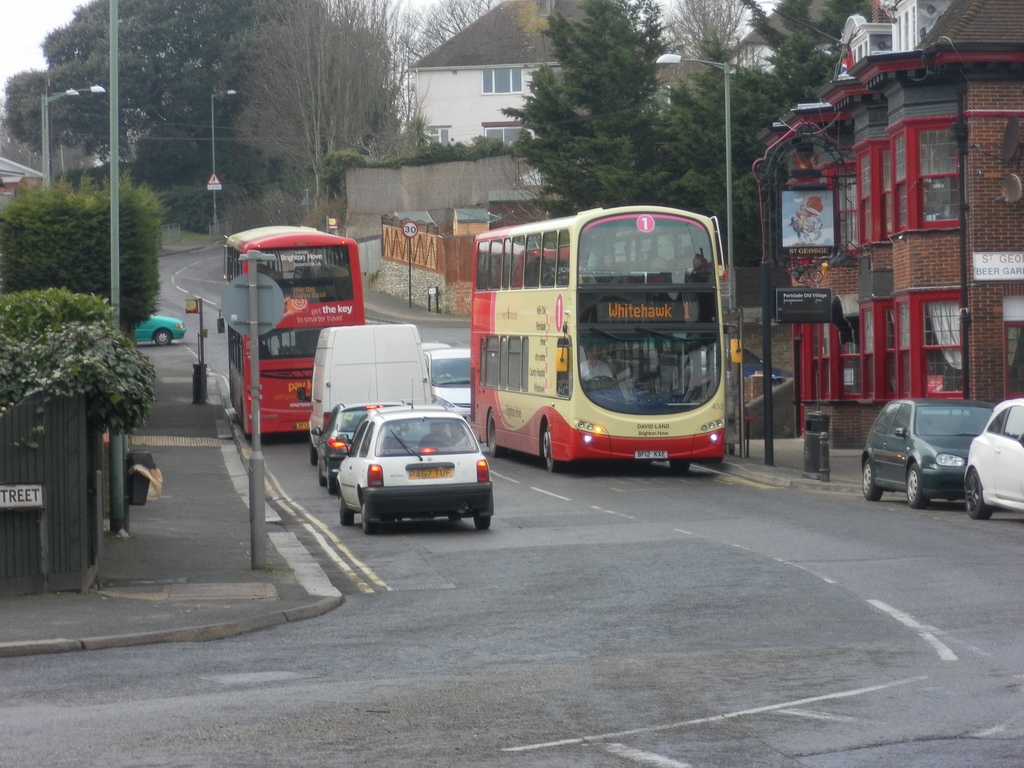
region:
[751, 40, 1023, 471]
red brick pub with red painted windows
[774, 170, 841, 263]
pub sign hanging in front of a pub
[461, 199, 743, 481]
yellow and red bus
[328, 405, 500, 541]
small light car has its brake lights on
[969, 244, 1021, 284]
pub sign advertises a beer garden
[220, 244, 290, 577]
circular traffic sign on a grey metal post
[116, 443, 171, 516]
grey trash can with a plastic bag inside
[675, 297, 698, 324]
bus number is displayed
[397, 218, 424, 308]
speed limit sign on the sidewalk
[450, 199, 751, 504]
The two level bus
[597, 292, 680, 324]
The digital display on the bus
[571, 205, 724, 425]
The large windshield on the bus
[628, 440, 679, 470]
The license plate on the bus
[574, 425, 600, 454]
The left headlight on the bus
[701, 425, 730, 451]
The right headlight on the bus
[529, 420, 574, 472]
The front wheel of the bus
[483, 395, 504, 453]
The back wheel of the bus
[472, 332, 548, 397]
The row of windows on the bus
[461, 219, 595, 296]
A row of windows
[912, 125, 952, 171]
glass window on the building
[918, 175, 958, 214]
glass window on the building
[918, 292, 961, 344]
glass window on the building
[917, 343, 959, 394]
glass window on the building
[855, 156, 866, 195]
glass window on the building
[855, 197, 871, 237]
glass window on the building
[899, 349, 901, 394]
glass window on the building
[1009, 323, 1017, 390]
glass window on the building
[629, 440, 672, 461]
license plate on the bus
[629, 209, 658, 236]
number 1 on the bus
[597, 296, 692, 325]
electric sign on the bus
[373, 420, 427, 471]
windshield wiper on the car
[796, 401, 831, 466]
trash can on the curb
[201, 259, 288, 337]
traffic sign on the pole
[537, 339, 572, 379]
yellow mirror on the bus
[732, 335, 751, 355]
yellow mirror on the bus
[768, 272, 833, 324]
sign hanging on the building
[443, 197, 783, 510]
Double Decker bus on street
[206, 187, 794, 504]
Two Double Decker buses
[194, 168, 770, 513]
Two Double Decker buses on street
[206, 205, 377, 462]
Bus stopped at curb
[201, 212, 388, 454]
Double Decker bus stopped on street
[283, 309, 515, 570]
Traffic stopped behind bus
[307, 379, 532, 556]
Cars stopped with brake lights on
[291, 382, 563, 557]
Car with brake lights on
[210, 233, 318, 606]
Rear view of traffic sign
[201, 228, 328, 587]
Traffic sign on pole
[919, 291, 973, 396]
A window on a building.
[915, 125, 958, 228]
A window on a building.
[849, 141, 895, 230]
A window on a building.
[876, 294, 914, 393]
A window on a building.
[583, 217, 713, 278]
glass is clean and clear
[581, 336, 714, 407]
glass is clean and clear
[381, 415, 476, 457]
glass is clean and clear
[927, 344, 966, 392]
glass is clean and clear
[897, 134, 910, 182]
glass is clean and clear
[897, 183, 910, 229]
glass is clean and clear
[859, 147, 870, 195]
glass is clean and clear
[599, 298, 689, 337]
the letters are golden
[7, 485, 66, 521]
the sign is white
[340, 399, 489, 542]
the car is white